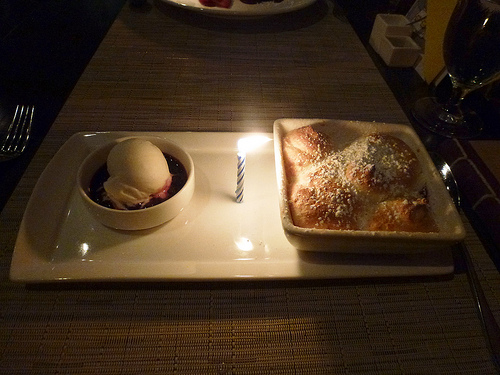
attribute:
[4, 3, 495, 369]
table runner — brown, bamboo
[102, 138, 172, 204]
ice cream — vanilla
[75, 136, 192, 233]
bowl — glass, round, white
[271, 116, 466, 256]
dish — square, ceramic, rectangular, white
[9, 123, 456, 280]
serving tray — white, rectangular, ceramic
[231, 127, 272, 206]
candle — blue, lit, white, burning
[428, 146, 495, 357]
spoon — metal, silver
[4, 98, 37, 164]
fork — metal, silver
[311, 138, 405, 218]
powedered sugar — white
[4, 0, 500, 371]
table — wooden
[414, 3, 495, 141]
glass — clear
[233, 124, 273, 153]
flame — glowing